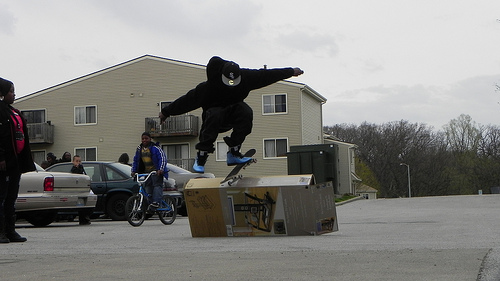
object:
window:
[71, 143, 116, 175]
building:
[0, 52, 340, 211]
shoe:
[225, 146, 252, 166]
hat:
[223, 60, 247, 83]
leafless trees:
[326, 115, 492, 198]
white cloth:
[350, 55, 492, 116]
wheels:
[121, 195, 178, 227]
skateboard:
[218, 151, 255, 187]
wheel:
[248, 155, 259, 165]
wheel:
[238, 173, 244, 178]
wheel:
[225, 179, 232, 189]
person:
[1, 73, 35, 247]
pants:
[0, 147, 26, 228]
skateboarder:
[153, 55, 303, 172]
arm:
[244, 67, 304, 85]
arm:
[156, 83, 206, 123]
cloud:
[102, 2, 262, 44]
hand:
[156, 107, 173, 127]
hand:
[287, 64, 305, 80]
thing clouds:
[158, 51, 340, 242]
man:
[160, 56, 303, 178]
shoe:
[190, 146, 205, 175]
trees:
[343, 97, 489, 213]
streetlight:
[400, 160, 414, 197]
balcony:
[139, 110, 216, 140]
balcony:
[13, 119, 50, 146]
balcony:
[157, 142, 197, 173]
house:
[1, 52, 358, 197]